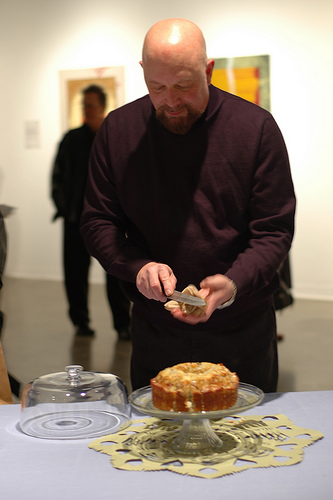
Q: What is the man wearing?
A: Long sleeves shirt.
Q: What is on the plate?
A: A cake.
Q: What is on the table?
A: Cake platter.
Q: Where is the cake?
A: Visible.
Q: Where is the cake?
A: On the stand.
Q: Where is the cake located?
A: On the table.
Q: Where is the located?
A: Next to the man.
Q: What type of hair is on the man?
A: Bald head.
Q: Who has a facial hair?
A: The man.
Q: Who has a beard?
A: The man.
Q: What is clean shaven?
A: The man's head.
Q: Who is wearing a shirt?
A: The man.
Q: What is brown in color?
A: The shirt.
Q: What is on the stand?
A: Cake.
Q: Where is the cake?
A: On cake plate.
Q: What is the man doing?
A: Holding a knife.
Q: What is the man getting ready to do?
A: Cut cake.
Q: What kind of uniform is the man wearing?
A: Black.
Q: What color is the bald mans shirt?
A: Purple.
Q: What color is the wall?
A: White.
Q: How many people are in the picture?
A: Two.